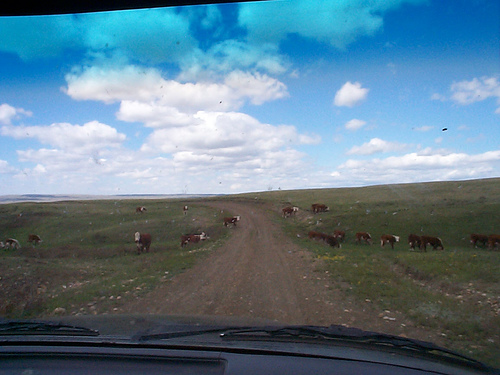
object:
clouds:
[0, 0, 499, 202]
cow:
[134, 205, 146, 214]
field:
[0, 177, 499, 365]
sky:
[0, 0, 499, 193]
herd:
[0, 201, 499, 255]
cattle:
[132, 230, 153, 254]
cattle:
[221, 213, 241, 228]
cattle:
[354, 230, 373, 243]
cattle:
[378, 232, 400, 247]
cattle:
[280, 203, 298, 218]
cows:
[131, 204, 241, 254]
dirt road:
[110, 192, 360, 326]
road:
[91, 189, 426, 342]